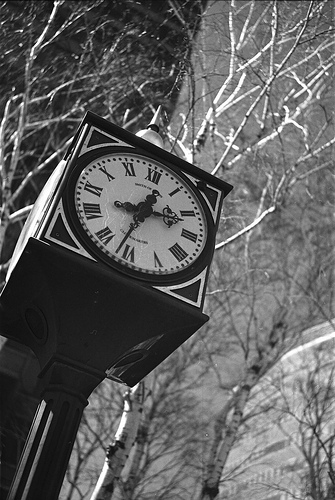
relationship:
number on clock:
[152, 247, 163, 267] [74, 149, 209, 276]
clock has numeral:
[63, 144, 216, 287] [177, 225, 200, 242]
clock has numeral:
[63, 144, 216, 287] [148, 247, 163, 269]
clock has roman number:
[63, 144, 216, 287] [94, 224, 113, 248]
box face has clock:
[32, 99, 236, 329] [63, 144, 216, 287]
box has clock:
[4, 116, 238, 390] [64, 144, 217, 281]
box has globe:
[0, 112, 234, 390] [135, 123, 166, 144]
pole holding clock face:
[10, 352, 104, 498] [9, 104, 225, 382]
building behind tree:
[204, 321, 323, 484] [214, 169, 282, 497]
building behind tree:
[204, 321, 323, 484] [280, 342, 325, 496]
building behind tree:
[204, 321, 323, 484] [316, 434, 325, 458]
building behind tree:
[204, 321, 323, 484] [216, 268, 260, 497]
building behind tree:
[204, 321, 323, 484] [285, 354, 325, 489]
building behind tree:
[204, 321, 323, 484] [319, 434, 325, 454]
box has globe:
[4, 116, 238, 390] [135, 123, 170, 151]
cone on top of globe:
[147, 99, 165, 130] [133, 123, 169, 147]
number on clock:
[166, 182, 183, 197] [75, 117, 216, 304]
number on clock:
[84, 201, 102, 221] [61, 118, 225, 317]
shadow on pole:
[42, 383, 84, 431] [0, 332, 103, 494]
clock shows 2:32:
[63, 144, 216, 287] [79, 151, 202, 275]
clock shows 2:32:
[27, 105, 240, 320] [71, 150, 211, 277]